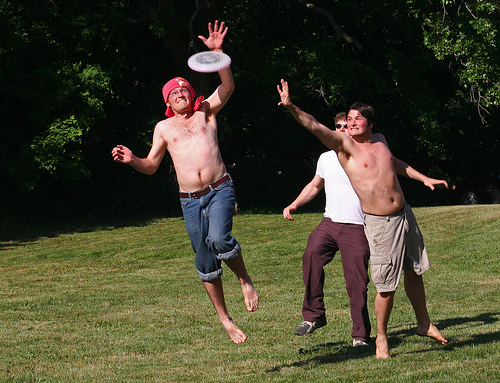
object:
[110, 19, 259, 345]
man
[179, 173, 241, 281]
jeans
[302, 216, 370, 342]
pants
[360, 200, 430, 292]
shorts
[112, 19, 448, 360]
men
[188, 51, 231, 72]
frisbee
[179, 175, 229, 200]
belt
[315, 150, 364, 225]
shirt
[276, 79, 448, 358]
man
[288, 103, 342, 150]
arm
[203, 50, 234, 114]
arm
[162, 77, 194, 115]
head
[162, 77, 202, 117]
shirt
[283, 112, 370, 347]
man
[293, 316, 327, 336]
foot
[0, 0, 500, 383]
ground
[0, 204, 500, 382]
field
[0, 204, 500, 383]
grass